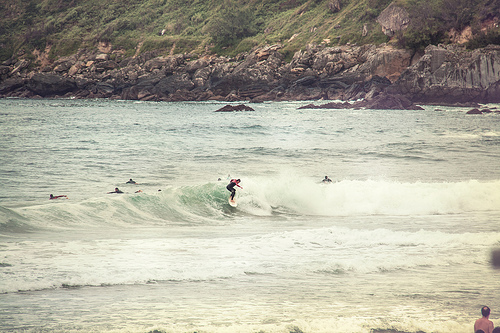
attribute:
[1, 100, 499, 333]
water — rising, beautiful view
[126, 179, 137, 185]
person — swimming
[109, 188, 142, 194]
person — paddling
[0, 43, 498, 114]
rocks — beautiful view, above water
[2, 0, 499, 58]
grass — beautiful view, hillside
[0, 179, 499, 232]
wave — crashing, coming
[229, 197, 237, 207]
board — white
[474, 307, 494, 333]
man — balding, on beach, enjoying